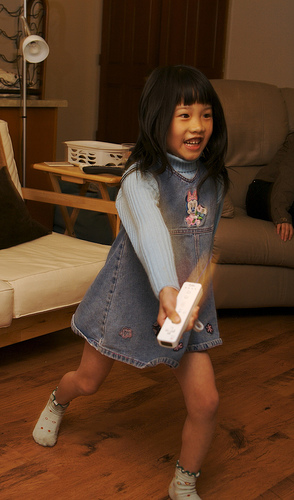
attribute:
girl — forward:
[30, 65, 243, 498]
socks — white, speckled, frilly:
[29, 391, 211, 499]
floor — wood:
[4, 310, 293, 499]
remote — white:
[153, 282, 213, 347]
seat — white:
[0, 120, 114, 345]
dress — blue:
[68, 145, 236, 368]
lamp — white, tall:
[19, 13, 49, 188]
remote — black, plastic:
[82, 162, 127, 176]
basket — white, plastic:
[62, 136, 127, 165]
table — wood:
[39, 160, 121, 239]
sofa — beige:
[210, 78, 292, 305]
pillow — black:
[2, 171, 54, 250]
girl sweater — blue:
[118, 168, 180, 291]